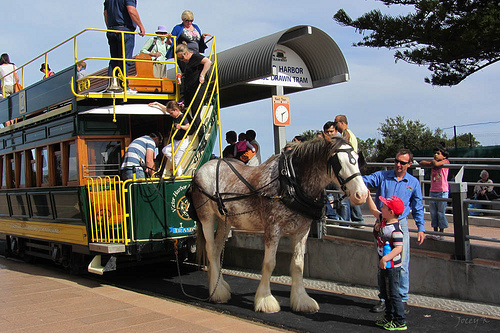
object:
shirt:
[358, 170, 426, 233]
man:
[357, 147, 433, 315]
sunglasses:
[393, 157, 413, 166]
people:
[167, 36, 215, 150]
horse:
[175, 128, 373, 317]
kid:
[366, 195, 411, 331]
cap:
[377, 195, 406, 215]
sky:
[2, 0, 500, 162]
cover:
[327, 153, 343, 175]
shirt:
[369, 221, 407, 272]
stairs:
[174, 98, 218, 120]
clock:
[271, 102, 290, 125]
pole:
[269, 123, 281, 155]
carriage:
[0, 18, 227, 286]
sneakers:
[383, 320, 408, 333]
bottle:
[381, 239, 394, 270]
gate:
[82, 173, 130, 242]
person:
[140, 26, 173, 83]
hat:
[152, 22, 172, 35]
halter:
[196, 152, 368, 216]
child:
[419, 144, 456, 235]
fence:
[325, 159, 497, 266]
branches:
[419, 57, 499, 84]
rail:
[0, 26, 183, 105]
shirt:
[426, 159, 449, 194]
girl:
[146, 101, 197, 169]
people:
[220, 128, 242, 160]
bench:
[70, 48, 154, 95]